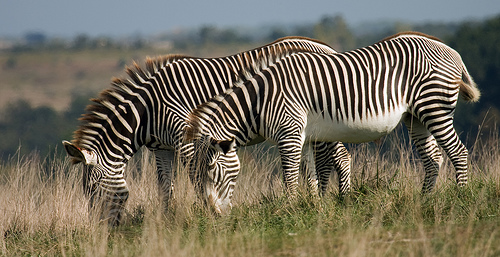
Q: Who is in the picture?
A: Two zebras.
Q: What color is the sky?
A: Blue.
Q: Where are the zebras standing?
A: In the grass.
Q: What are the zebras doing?
A: Eating.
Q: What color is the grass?
A: Green.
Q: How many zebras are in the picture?
A: Two.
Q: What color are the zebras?
A: Black and white.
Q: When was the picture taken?
A: During the day.